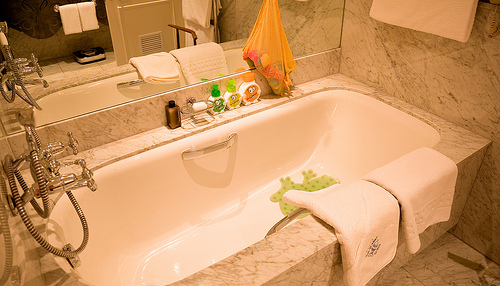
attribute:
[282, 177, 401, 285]
towel — white, for bath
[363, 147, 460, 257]
towel — white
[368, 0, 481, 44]
towel — white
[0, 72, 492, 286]
bathtub — white, clean, empty, elegant looking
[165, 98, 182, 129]
bottle — brown, small, copper colored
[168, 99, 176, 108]
cap — black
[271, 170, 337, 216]
bath mat — frog shaped, green, anti-slip, for children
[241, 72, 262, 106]
bottle — orange, white, of soap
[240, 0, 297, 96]
bag — orange, mesh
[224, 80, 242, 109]
bottle — of soap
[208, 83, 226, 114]
bottle — of soap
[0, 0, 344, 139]
mirror — glass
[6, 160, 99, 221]
handle — silver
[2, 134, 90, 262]
hose — silver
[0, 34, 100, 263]
faucet — silver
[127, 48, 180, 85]
towel — white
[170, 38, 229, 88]
towel — white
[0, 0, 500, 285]
stone — gray